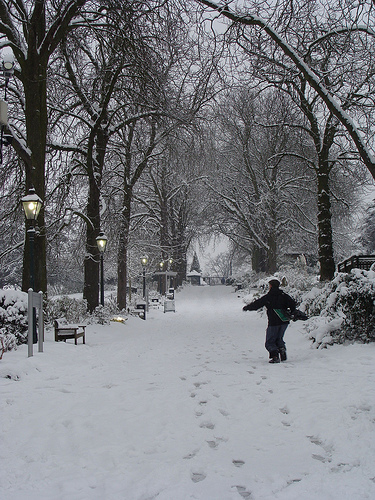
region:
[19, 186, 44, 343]
a black lamp post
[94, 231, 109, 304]
a black lamp post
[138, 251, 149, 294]
a black lamp post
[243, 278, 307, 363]
a person in the snow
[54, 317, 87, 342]
a snow covered bench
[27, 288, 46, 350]
a white sign on posts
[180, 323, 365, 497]
foot tracks in the snow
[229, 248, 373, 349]
a row of snow covered bushes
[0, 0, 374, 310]
lots of snow covered trees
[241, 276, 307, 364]
a person wearing a black coat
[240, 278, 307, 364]
a man carrying a surfboard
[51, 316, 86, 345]
a bench covered in snow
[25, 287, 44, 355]
a small silver sign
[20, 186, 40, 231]
a light on a post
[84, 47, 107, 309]
trunk of a tall tree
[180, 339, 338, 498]
tracks in the snow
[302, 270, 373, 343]
bushes covered in snow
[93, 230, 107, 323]
a lamp on a black post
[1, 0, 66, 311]
a large tree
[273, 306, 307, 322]
a green snowboard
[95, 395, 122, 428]
Small patch of white snow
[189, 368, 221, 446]
Foot prints in the snow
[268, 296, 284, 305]
Black coat of civilian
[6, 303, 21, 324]
Patch of snow on green bush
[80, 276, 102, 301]
Brown oak of the tree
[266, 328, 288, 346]
Pants of the civilian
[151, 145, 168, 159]
A branch on the tree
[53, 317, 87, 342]
Brown bench on the snow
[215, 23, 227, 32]
Small patch of white sky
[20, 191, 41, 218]
Light of the street light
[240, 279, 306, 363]
A guy is walking in the snow.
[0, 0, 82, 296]
The large tree does not have any leaves.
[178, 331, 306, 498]
The footprints of several people.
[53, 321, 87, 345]
A bench is outside in the snow.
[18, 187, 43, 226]
A bright lamp is outside in the snow.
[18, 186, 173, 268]
Five lamps are visible in the frozen city.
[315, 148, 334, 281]
The black trunk of a black tree.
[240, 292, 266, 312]
The left arm of one person.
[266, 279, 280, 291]
The head of an average sized person.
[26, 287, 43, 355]
A metallic banner is in the park.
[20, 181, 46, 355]
Lit street light pole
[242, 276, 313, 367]
Man heavily dressed with snowboard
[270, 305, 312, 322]
Green snowboard held in arm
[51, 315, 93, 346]
Snow covered bench outside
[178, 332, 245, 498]
Pair of footsteps in the snow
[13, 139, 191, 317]
Parallel line of trees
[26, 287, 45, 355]
Wooden signpost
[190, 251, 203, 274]
Pine shaped snow tree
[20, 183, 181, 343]
Parallel line of street lamps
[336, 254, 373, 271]
Wooden rail steps